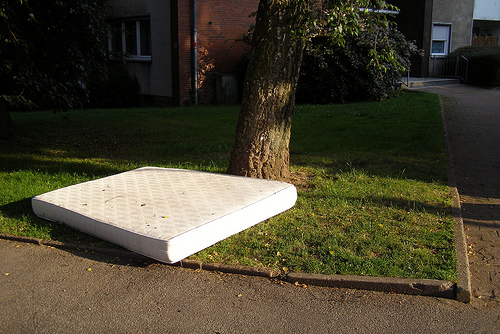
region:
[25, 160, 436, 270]
There is a mattress lying on the grass.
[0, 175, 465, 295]
There is a curb bordering the grass.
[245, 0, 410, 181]
There is a tree next to the mattress.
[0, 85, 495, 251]
There are shadows on the ground.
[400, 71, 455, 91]
There is a puddle of water on the ground.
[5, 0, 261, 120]
There is a brick building behind the tree.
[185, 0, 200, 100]
There is a metal pipe on the side of the building.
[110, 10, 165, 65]
There is a window on the front of the building.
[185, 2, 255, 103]
There is a shadow on the side of the building.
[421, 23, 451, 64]
There is a white framed window.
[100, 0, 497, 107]
brick apartment building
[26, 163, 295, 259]
discarded old mattress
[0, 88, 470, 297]
area of green lawn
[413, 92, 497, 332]
paved walk leading to building entrance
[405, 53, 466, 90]
small step with rails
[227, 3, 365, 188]
stout tree trunk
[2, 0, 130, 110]
bushy area on side of building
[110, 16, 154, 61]
three section window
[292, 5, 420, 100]
large bush next to steps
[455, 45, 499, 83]
small bush next to steps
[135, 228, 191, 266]
edge of mattress on grass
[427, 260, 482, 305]
edge of curve by tree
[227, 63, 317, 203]
bark of tree by mattress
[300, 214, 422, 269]
grass by the tree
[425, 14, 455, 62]
window of the building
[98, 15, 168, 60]
window by the bush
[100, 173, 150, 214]
black material on mattress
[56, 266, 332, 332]
asphalt road by grass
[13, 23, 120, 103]
top of tree by building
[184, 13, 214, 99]
drainage on side of house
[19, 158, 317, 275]
mattress laying on the grass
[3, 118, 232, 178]
shadow on the grass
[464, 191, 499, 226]
shadow on the ground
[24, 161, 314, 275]
white mattress on the ground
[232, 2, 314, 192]
thick brown tree trunk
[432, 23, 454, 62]
window on the side of the building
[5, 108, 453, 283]
green grass on the ground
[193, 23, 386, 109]
bushes on the side of the building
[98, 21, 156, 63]
white lines on the window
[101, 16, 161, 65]
window is dark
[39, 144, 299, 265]
white mattress beside tree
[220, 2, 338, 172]
tree trunk beside mattress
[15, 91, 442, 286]
grass mattress is laying on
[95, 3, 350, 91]
building behind tree and mattress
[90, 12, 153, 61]
windows of building behind tree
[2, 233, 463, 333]
sidewalk in front of mattress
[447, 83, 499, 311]
sidewalk beside tree trunk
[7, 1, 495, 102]
shrubbery around the buildings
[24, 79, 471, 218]
shadows on grass from tree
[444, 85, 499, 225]
shadows on the sidewalk